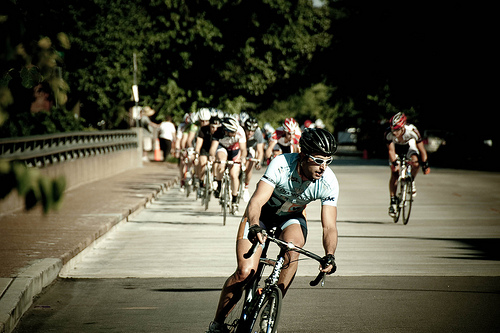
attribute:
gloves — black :
[306, 255, 338, 287]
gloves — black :
[246, 224, 261, 244]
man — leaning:
[212, 118, 366, 326]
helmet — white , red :
[281, 116, 293, 131]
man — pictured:
[206, 124, 362, 299]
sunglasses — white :
[307, 150, 335, 167]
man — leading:
[208, 110, 370, 308]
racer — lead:
[206, 125, 339, 330]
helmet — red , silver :
[386, 113, 413, 138]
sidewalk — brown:
[1, 167, 186, 330]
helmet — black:
[299, 124, 341, 159]